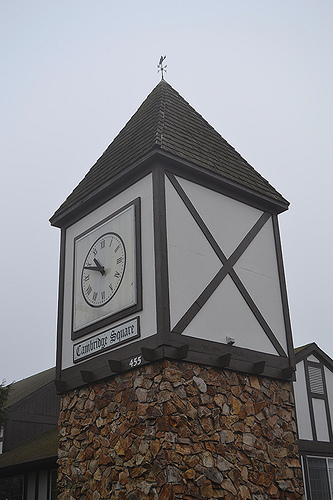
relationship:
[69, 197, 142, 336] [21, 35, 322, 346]
clock on tower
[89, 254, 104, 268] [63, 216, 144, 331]
hand of clock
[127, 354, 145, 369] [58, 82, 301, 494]
455 on building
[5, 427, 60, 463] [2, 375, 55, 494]
roof on building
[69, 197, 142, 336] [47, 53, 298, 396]
clock on clock tower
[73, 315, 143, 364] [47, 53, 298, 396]
sign on clock tower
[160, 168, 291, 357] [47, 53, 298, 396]
x on clock tower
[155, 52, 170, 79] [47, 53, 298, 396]
weather vein on clock tower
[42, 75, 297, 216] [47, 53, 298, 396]
roof on clock tower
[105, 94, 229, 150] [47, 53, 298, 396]
shingles on clock tower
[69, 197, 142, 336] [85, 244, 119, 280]
clock reads 22:49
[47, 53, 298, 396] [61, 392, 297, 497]
clock tower partly made of stone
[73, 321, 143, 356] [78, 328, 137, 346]
sign reads cambridge square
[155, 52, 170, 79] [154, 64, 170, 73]
weather vein has arrows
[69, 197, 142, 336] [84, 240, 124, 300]
clock has roman numerals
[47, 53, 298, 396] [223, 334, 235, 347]
clock tower has light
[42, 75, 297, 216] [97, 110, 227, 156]
roof has shingles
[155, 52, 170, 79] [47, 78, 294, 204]
weather vein on roof top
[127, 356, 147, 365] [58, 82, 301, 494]
number 455 on building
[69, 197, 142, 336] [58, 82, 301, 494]
clock on side of building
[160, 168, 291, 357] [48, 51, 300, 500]
x on side of building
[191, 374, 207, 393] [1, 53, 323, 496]
rock stuck onto building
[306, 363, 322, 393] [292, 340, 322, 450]
air vent ventilating attic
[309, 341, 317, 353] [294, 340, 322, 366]
peak adorning roof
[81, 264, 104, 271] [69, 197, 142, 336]
hand mounted on clock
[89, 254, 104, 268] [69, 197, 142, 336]
hand mounted on clock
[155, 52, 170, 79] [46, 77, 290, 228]
weather vein topping roof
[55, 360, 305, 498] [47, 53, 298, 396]
base supporting clock tower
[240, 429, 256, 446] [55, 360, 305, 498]
rock cemented onto base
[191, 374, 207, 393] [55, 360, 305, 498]
rock cemented onto base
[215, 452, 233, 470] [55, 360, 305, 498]
rock cemented onto base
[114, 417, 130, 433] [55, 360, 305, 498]
rock cemented onto base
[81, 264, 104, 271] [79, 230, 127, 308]
hand mounted on clock face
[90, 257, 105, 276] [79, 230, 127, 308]
hand mounted on clock face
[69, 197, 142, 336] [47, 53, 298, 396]
clock adorning clock tower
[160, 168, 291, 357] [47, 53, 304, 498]
x adorning clock tower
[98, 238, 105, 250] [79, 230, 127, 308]
roman numeral painted on clock face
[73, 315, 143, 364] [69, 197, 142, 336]
sign hanging underneath clock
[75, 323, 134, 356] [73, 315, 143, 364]
cambridge square painted on sign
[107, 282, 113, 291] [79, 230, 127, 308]
roman numeral painted on clock face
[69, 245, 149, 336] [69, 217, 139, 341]
clock enclosed in a square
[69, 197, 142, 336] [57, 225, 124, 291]
clock reads 10:49